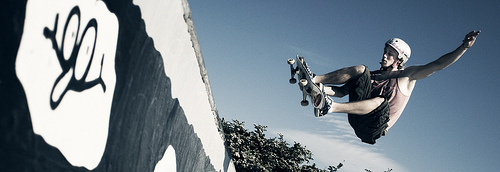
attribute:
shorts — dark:
[345, 66, 388, 144]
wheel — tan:
[296, 97, 318, 106]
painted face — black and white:
[13, 0, 120, 170]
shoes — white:
[272, 33, 357, 111]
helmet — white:
[379, 36, 412, 68]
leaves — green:
[244, 141, 282, 162]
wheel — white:
[286, 56, 300, 68]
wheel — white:
[286, 72, 298, 87]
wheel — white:
[297, 74, 310, 88]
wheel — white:
[297, 97, 309, 109]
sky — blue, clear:
[198, 7, 494, 170]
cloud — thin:
[258, 124, 407, 169]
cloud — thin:
[321, 110, 365, 145]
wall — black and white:
[0, 2, 237, 169]